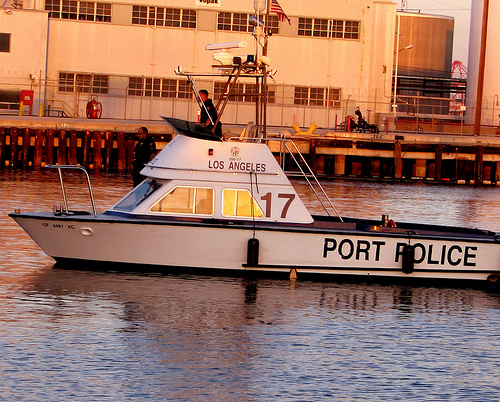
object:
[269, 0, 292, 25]
flag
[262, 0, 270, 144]
pole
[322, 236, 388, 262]
word port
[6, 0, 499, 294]
boat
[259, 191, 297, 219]
number 17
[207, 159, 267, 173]
los angeles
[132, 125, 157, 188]
police officer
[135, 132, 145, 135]
glasses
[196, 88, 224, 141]
police officer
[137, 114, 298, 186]
deck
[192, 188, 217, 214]
window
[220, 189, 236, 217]
window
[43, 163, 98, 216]
railing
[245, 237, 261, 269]
anchor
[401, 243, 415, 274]
anchor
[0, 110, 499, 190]
harbor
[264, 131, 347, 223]
ladder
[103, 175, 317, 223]
cabin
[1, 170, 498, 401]
water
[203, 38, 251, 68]
radar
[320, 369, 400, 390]
ripples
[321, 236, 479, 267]
writing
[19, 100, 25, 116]
post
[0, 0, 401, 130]
building